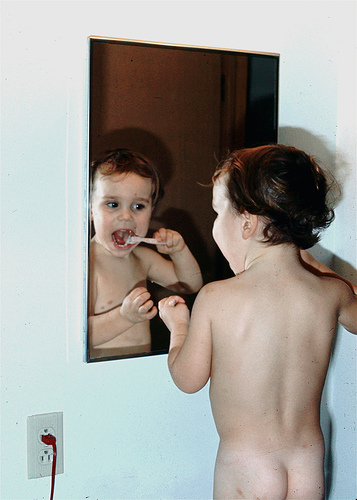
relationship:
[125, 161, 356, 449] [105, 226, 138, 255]
toddler brushing teeth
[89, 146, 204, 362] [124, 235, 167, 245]
toddler holding toothbrush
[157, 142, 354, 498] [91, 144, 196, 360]
child looking at reflection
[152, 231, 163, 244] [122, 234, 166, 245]
finger curled around toothbrush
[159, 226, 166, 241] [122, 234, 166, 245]
finger curled around toothbrush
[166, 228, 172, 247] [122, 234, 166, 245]
finger curled around toothbrush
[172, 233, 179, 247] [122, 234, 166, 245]
finger curled around toothbrush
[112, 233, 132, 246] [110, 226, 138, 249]
teeth in mouth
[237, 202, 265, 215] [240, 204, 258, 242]
hair over ear